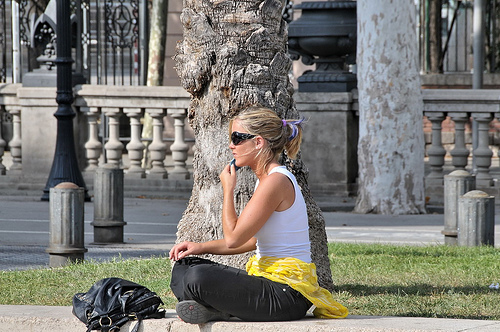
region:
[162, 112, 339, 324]
A woman in the photo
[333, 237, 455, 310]
Grass on the field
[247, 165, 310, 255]
A white vest in the photo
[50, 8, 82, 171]
Pillars on the building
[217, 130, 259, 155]
Glasses on the woman eyes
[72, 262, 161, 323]
A handbag on the floor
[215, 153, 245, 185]
A phone in the hands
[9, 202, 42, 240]
A road with tarmac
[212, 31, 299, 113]
A tree trunk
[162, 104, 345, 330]
A woman seated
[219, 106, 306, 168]
a blonde wearing sunglasses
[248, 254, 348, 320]
a yellow jacket tied around a womans waist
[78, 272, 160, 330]
a woman's black purse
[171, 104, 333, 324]
a woman on her cell phone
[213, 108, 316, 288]
a woman in a white tank top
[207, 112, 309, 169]
a woman with a purple head tie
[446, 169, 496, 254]
a stone pillar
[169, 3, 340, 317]
a woman sitting behind a tree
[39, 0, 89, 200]
a tall black lamp post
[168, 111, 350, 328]
a woman sitting on concrete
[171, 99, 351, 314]
woman sitting down by a tree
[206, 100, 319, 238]
woman talking on cell phone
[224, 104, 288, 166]
woman wearing black sunglasses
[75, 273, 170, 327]
black purse on ground in front of woman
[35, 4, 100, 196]
decorative black metal pole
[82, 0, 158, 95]
iron gates near building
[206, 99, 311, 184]
woman with blonde hair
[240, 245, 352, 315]
yellow clothing wrapped around woman's waist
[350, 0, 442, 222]
tall white tree trunk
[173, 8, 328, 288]
large tree trunk behind woman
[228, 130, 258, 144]
black glasses on the woman's face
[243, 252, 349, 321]
yellow jacket tied around her waist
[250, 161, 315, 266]
white tank top on the woman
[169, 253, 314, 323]
black pants on the woman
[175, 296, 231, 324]
black shoe on the woman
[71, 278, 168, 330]
black purse on the sidewalk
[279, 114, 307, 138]
purple ribbon in the woman's hair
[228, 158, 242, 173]
cellphone in the woman's hand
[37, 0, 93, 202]
black street pole by the street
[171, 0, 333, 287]
large tree trunk behind the woman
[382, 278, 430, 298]
shadow in the grass.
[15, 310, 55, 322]
curb near the street.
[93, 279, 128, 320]
black bag on curb.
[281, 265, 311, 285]
yellow shirt on woman's waist.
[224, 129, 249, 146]
sunglasses on woman's face.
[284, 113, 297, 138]
ribbon in woman's hair.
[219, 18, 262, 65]
trunk of the tree.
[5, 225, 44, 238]
white line on the street.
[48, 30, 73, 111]
light pole on the curb.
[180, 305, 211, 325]
sole of the shoe.